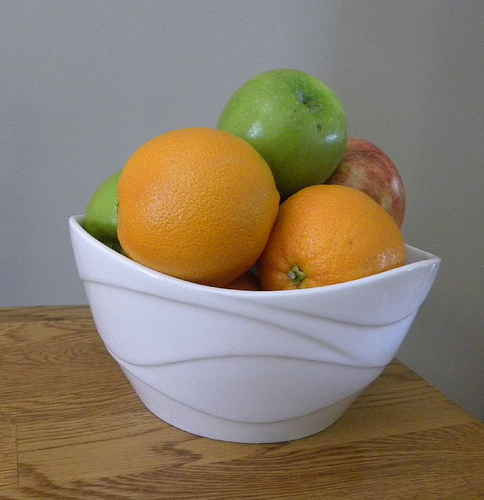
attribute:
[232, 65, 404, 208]
apples — green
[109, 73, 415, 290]
fruit — several 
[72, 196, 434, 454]
bowl — white, small, porcelain, glass, white glass, ceramic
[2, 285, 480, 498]
table — wooden, wood, brown,  wooden , table 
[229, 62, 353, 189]
apple — granny smith, green granny smith, red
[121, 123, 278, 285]
orange — large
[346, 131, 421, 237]
apple — red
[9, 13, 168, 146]
wall — grey, gray, light grey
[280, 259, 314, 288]
stem — small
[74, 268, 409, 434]
design — wavy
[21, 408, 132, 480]
wood — brown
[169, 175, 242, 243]
texture — porous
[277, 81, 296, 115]
specks — light yellow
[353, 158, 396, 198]
undertones — yellow